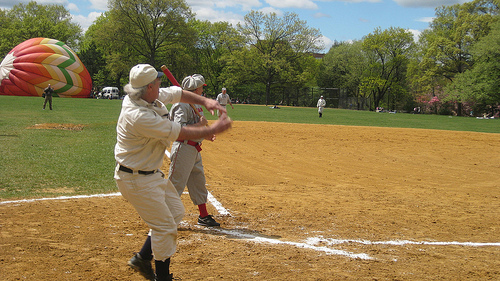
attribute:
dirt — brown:
[281, 157, 377, 212]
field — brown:
[273, 117, 465, 203]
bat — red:
[162, 62, 216, 142]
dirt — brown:
[327, 121, 389, 206]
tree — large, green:
[218, 10, 324, 110]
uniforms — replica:
[113, 99, 223, 251]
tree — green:
[368, 39, 403, 85]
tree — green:
[435, 26, 473, 92]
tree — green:
[248, 30, 288, 94]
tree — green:
[110, 9, 176, 71]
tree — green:
[318, 55, 362, 105]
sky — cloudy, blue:
[6, 2, 443, 52]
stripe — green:
[57, 40, 73, 100]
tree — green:
[96, 0, 195, 106]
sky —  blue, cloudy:
[344, 7, 389, 34]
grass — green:
[1, 93, 499, 206]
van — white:
[93, 80, 117, 97]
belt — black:
[114, 163, 161, 178]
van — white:
[95, 85, 118, 97]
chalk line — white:
[203, 203, 448, 263]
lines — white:
[243, 223, 494, 264]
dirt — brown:
[236, 124, 490, 274]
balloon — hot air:
[3, 34, 150, 91]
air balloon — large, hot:
[1, 35, 97, 95]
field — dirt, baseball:
[1, 122, 497, 279]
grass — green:
[18, 124, 111, 183]